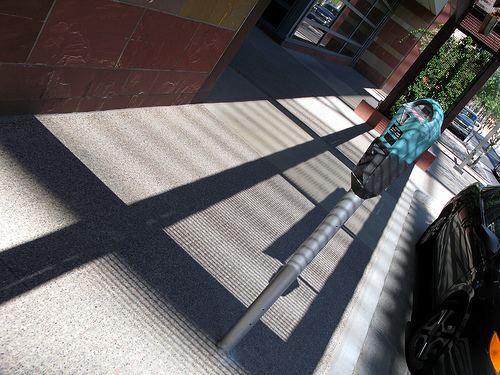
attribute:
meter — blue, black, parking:
[359, 74, 426, 213]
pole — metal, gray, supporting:
[266, 196, 338, 304]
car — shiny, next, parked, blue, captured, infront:
[429, 197, 477, 316]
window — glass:
[483, 188, 497, 233]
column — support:
[461, 44, 472, 102]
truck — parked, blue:
[458, 108, 478, 147]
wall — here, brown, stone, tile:
[72, 12, 142, 81]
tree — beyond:
[425, 51, 475, 122]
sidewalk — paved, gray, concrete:
[155, 122, 246, 240]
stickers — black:
[373, 126, 424, 172]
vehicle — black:
[431, 189, 499, 340]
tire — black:
[398, 299, 451, 354]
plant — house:
[415, 47, 476, 103]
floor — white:
[297, 60, 360, 154]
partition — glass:
[304, 1, 330, 54]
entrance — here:
[256, 13, 319, 88]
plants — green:
[413, 37, 472, 120]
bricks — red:
[65, 13, 214, 116]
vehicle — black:
[399, 178, 493, 370]